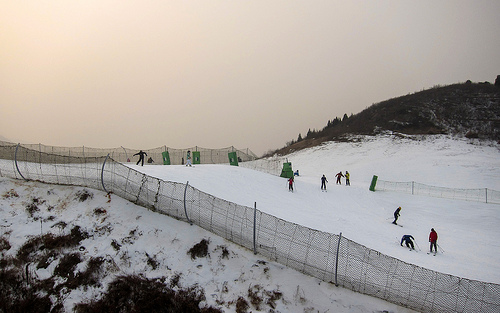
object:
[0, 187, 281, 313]
plants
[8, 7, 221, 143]
sunset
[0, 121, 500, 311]
view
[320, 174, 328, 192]
outfit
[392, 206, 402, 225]
man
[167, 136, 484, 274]
field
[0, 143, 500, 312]
fence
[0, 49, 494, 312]
camera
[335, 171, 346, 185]
arms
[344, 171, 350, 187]
arms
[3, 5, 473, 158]
sky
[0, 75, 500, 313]
hill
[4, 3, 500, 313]
picture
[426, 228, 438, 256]
person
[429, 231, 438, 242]
coat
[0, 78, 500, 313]
landscape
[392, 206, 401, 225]
skier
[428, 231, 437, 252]
suit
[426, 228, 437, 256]
skier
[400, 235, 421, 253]
ski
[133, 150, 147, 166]
person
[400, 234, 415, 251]
people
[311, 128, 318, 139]
trees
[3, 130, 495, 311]
snow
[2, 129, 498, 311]
ground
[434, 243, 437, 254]
poles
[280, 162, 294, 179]
sign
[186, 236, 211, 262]
rock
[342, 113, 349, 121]
tree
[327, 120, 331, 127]
tree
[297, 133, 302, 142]
tree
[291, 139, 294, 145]
tree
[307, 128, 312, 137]
tree